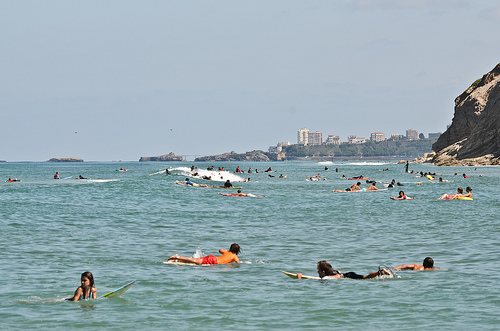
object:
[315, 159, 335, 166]
wave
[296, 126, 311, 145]
building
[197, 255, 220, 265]
swim trunks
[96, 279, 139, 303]
surfboard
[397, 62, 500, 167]
cliff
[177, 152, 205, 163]
bridge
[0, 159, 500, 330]
ocean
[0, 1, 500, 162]
sky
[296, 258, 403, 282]
guy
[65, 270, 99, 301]
girl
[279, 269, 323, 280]
surfboard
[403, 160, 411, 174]
person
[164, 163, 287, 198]
people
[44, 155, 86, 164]
rock formation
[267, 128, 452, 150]
city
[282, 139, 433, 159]
trees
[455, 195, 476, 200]
inner tube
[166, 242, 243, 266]
boy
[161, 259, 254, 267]
surfboard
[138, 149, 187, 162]
island